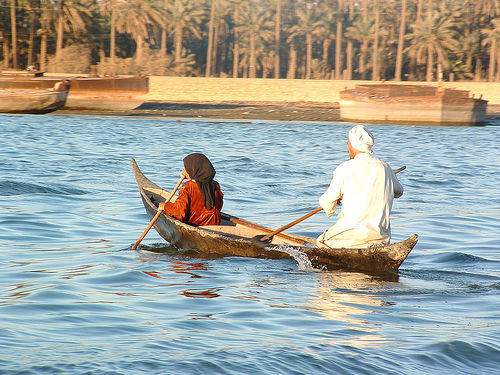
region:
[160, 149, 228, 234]
woman is wearing head scarf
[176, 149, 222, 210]
head scarf is black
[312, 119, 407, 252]
man is wearing turban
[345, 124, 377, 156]
turban is white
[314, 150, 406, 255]
man's robe is white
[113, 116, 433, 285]
couple is riding in boat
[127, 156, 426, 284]
boat is brown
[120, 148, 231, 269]
woman is holding an oar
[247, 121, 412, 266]
man is holding an oar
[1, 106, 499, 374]
boat is in the water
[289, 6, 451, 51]
a group of palm trees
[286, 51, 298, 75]
the trunk of a palm tree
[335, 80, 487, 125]
a boat on the shore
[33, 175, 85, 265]
small waves in the water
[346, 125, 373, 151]
a man wearing a white head skarf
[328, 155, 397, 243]
a man in a white shirt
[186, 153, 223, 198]
a woman wearing a black head skarf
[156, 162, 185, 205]
hands holding a pole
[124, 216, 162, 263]
a wooden pole in the water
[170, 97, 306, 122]
dark dirt on a shore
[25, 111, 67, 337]
a lake on the image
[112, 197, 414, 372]
a boat is on the image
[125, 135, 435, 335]
a man and a woman on the boat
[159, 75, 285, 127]
land on the image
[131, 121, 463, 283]
people are riding on a boat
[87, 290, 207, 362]
they are riding on a lake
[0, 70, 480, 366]
a beautiful picture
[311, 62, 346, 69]
their is vegetation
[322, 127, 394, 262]
the guy is dressed in white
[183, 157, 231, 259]
the lady dressed in arabic dresssing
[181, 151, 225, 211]
Brown head wrap on person's head.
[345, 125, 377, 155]
White head wrap on man's head.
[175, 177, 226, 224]
Brown shirt worn by person in brown head wrap.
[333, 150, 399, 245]
White shirt worn by man in white head wrap.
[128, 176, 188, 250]
Row stick held by person in brown head wrap.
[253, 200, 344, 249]
Row stick in hand of person in white.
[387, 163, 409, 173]
Handle of row stick of person in white.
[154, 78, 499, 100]
Light tan sand in front of trees.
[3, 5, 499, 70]
Trees in background of photo.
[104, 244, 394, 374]
Water ripples of reflection of people on boat.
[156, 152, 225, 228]
woman with brown scarf on head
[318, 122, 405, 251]
man in white robe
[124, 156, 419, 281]
man and woman in canoe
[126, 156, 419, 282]
brown wooden canoe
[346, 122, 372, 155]
man wearing white hat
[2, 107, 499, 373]
calm blue water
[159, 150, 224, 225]
woman wearing orange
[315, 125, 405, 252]
man rowing canoe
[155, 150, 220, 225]
woman holding paddle in water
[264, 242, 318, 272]
water splashing around oar